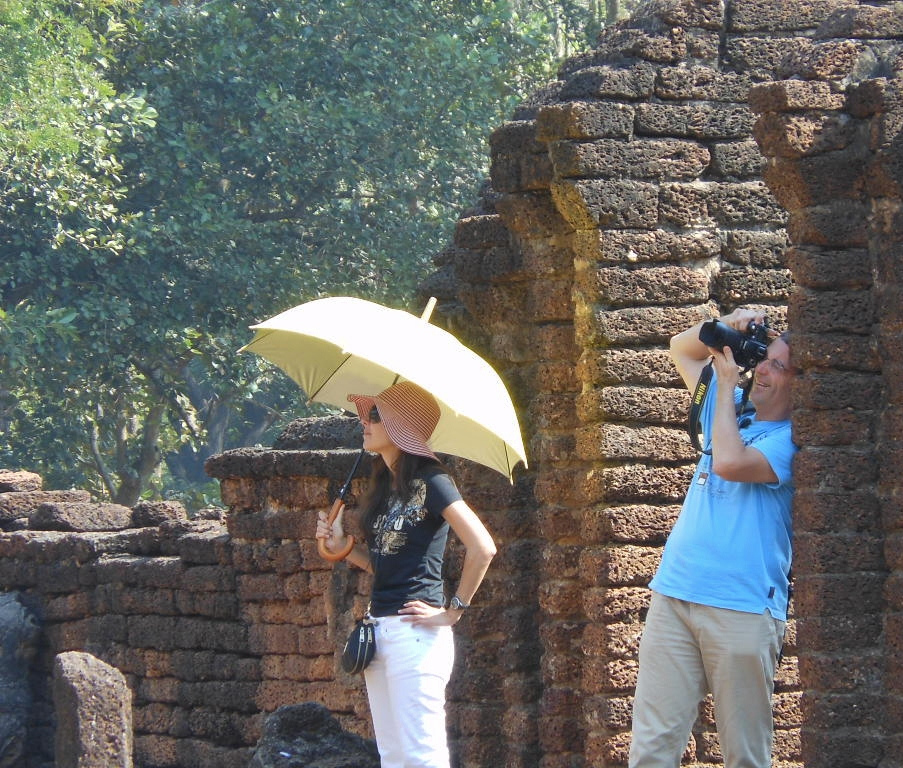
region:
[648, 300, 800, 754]
The man using the camera is smiling.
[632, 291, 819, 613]
a man looks through a camera's lens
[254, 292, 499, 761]
woman holding umbrella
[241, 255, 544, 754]
Woman with a yellow umbrella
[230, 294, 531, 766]
woman holding yellow umbrella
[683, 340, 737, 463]
The camera strap says Nikon.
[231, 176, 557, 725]
A woman wears a hat and carries a yellow umbrella outside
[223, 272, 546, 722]
Woman holding umbrella with right hand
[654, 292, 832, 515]
Man taking pictures with camera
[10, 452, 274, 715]
Old mud brick wall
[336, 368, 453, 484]
Woman wearing pink hat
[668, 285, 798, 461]
Man holding expensive camera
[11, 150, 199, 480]
Leafy trees in background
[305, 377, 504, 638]
Woman with hand on hip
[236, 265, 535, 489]
Unfolded yellow umbrella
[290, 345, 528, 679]
Woman wearing black t-shirt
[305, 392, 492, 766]
Woman wearing white pants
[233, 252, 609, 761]
WOMAN WEARING PURSE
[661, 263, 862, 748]
MAN WEARING KHAKI PANTS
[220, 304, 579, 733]
WOMAN IN RED & WHITE STRIPED HAT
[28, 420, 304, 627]
BRICK WALL SURROUNDING THE COUPLE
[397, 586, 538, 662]
WATCH ON WOMEN'S RIGHT HAND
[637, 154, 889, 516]
MAN TAKING PHOTOGRAPHS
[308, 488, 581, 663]
WOMEN WITH HAND ON HER HIP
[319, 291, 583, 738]
WOMEN HOLDING YELLOW UMBRELLA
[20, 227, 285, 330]
TREE WITH GREEN LEAVES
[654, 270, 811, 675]
man in blue polo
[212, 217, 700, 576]
a yellow umbrella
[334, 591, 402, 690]
woman carrying ablack bag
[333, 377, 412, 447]
woman has worn shades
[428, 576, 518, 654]
woman has a watch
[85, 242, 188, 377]
trees are were they are standing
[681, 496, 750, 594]
man has worn a blue tshirt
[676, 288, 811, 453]
man is holding camera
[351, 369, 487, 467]
woman is wearing a hat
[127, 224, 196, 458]
it is sunny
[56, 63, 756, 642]
it seems to be sunny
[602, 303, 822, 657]
the man seems to be taking a picture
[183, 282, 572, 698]
the woman is holding an umbrella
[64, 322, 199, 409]
the trees are green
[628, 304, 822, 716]
the man has a blue shirt on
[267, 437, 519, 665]
the woman has a black shirt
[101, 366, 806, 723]
it is an outdoor scene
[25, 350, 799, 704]
it is a daytime scene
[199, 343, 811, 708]
there are two people in the picture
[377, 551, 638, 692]
the woman has a watch on her hand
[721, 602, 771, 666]
outline of rectangular object in man's pocket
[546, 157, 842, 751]
archway made of weathered brick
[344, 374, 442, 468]
red and white striped sun hat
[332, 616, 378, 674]
small black zippered bag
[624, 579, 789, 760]
tan khaki pants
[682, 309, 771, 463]
camera with attached strap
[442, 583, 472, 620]
watch on woman's left wrist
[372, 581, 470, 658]
woman's hand on her hip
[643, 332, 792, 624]
man wearing blue shirt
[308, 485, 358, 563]
wooden umbrella handle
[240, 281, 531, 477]
A yellow umbrella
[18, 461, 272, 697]
old stone walls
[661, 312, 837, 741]
a man taking a picture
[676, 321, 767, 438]
a professional camera